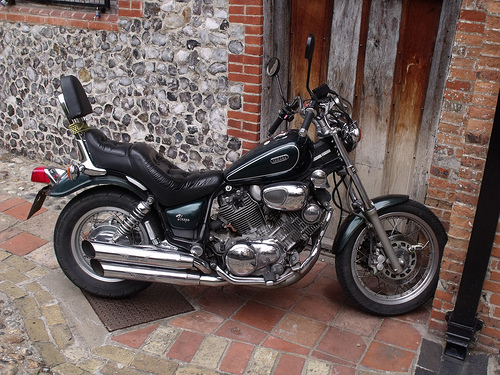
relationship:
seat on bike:
[82, 129, 228, 199] [23, 32, 446, 315]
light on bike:
[24, 163, 56, 187] [23, 32, 446, 315]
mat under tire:
[55, 289, 221, 325] [32, 179, 180, 293]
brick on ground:
[314, 322, 369, 364] [0, 196, 432, 373]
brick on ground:
[222, 340, 254, 372] [0, 196, 432, 373]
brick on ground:
[169, 330, 205, 360] [0, 196, 432, 373]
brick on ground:
[291, 289, 343, 325] [0, 196, 432, 373]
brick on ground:
[0, 197, 25, 213] [0, 196, 432, 373]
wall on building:
[76, 35, 229, 146] [6, 1, 264, 205]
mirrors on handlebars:
[257, 32, 346, 104] [247, 79, 355, 139]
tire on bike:
[334, 198, 447, 316] [23, 32, 446, 315]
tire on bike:
[51, 184, 164, 301] [23, 32, 446, 315]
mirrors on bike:
[265, 27, 314, 78] [23, 32, 446, 315]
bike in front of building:
[23, 32, 446, 315] [3, 6, 494, 352]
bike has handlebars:
[23, 32, 446, 315] [299, 100, 320, 139]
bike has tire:
[23, 32, 446, 315] [328, 194, 451, 319]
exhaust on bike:
[82, 241, 224, 286] [23, 32, 446, 315]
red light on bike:
[31, 167, 56, 184] [23, 32, 446, 315]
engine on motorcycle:
[212, 192, 322, 276] [26, 70, 494, 363]